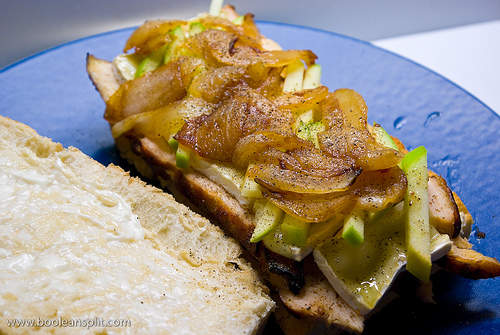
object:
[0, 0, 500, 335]
lunch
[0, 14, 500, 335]
plate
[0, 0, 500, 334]
bread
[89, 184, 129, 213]
butter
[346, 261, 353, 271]
cheese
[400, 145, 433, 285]
apple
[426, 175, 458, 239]
pepper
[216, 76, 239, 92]
onions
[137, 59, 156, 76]
green pepper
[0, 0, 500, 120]
table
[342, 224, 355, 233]
apples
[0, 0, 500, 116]
ground